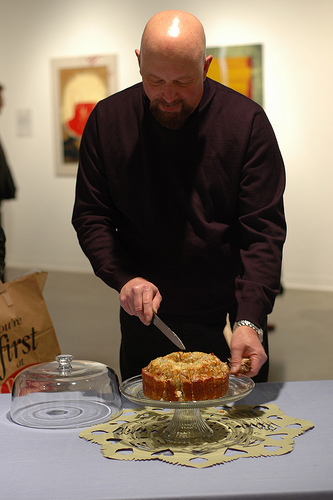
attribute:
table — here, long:
[1, 376, 327, 499]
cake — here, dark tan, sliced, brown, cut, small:
[144, 347, 226, 398]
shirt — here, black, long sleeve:
[71, 80, 290, 322]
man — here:
[78, 8, 286, 384]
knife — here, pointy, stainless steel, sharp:
[150, 314, 187, 351]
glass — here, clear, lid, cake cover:
[14, 353, 115, 427]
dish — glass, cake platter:
[119, 375, 251, 447]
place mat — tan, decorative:
[82, 397, 315, 474]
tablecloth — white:
[4, 385, 333, 499]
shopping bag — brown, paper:
[2, 276, 65, 396]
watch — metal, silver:
[237, 316, 271, 342]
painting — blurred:
[45, 58, 122, 174]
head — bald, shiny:
[138, 13, 206, 114]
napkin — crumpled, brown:
[221, 316, 255, 374]